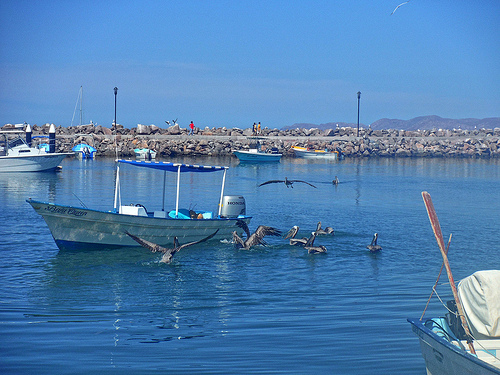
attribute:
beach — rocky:
[0, 125, 499, 158]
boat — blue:
[232, 146, 284, 165]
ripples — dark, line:
[132, 274, 319, 354]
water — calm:
[158, 263, 284, 316]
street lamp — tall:
[111, 84, 120, 94]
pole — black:
[112, 97, 119, 127]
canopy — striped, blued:
[110, 155, 227, 224]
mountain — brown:
[263, 105, 498, 138]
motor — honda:
[218, 189, 251, 221]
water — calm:
[359, 170, 498, 200]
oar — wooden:
[384, 177, 482, 337]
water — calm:
[99, 289, 158, 325]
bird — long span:
[252, 172, 321, 200]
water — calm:
[2, 156, 498, 372]